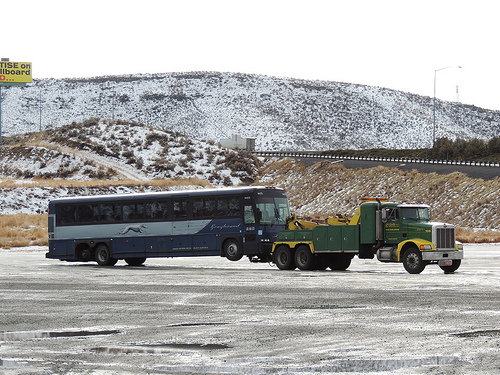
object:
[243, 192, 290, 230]
windshield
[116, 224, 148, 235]
logo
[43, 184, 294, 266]
bus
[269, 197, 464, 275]
tow truck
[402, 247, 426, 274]
tire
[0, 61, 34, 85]
sign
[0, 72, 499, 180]
hill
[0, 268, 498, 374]
frozen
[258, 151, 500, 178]
road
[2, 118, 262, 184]
brush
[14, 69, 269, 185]
snow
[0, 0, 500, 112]
sky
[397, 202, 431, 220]
windshield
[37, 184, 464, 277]
greyhound bus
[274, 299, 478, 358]
snow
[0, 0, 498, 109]
clouds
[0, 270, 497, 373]
ground